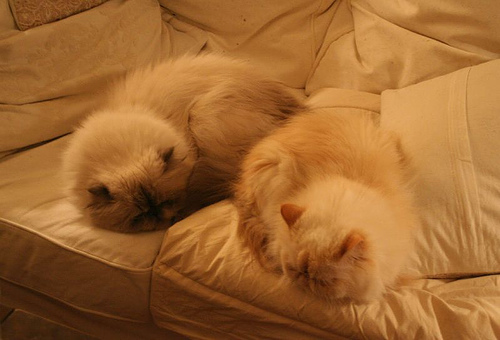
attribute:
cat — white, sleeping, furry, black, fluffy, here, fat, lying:
[57, 48, 315, 231]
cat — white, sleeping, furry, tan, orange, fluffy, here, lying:
[232, 101, 425, 303]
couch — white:
[7, 5, 494, 331]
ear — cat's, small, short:
[82, 179, 110, 208]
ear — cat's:
[157, 144, 184, 170]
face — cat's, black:
[87, 144, 184, 232]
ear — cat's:
[340, 232, 366, 260]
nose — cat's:
[153, 210, 166, 229]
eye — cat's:
[129, 211, 145, 225]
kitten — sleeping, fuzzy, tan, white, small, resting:
[49, 36, 287, 226]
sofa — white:
[10, 0, 493, 305]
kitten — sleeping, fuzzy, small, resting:
[222, 96, 428, 307]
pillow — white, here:
[375, 50, 500, 288]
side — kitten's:
[383, 2, 498, 334]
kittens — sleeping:
[67, 58, 415, 302]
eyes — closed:
[128, 195, 178, 223]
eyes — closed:
[286, 259, 341, 288]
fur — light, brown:
[250, 124, 399, 286]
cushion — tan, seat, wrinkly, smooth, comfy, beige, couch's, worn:
[155, 197, 500, 336]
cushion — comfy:
[3, 126, 197, 310]